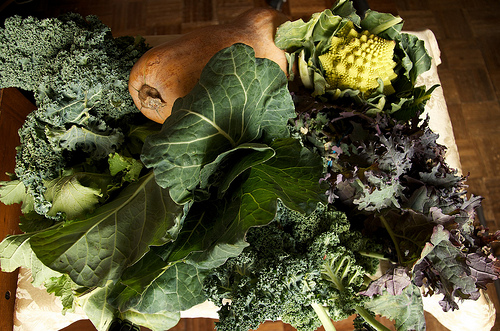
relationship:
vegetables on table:
[3, 10, 496, 325] [0, 30, 494, 328]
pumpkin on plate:
[127, 2, 304, 127] [10, 27, 495, 329]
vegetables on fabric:
[3, 10, 496, 325] [11, 29, 500, 331]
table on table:
[0, 0, 493, 327] [0, 30, 494, 328]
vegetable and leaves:
[314, 26, 405, 97] [289, 6, 319, 81]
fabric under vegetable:
[11, 29, 492, 329] [173, 97, 388, 262]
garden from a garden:
[0, 10, 490, 330] [14, 65, 492, 331]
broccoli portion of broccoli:
[205, 206, 368, 330] [205, 206, 368, 328]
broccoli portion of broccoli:
[205, 206, 368, 330] [0, 12, 135, 215]